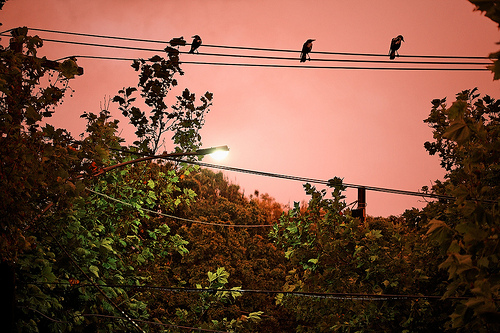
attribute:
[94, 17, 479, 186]
sky — pink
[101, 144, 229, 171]
street light — on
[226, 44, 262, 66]
wires — electrical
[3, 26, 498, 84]
wires — three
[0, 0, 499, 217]
sky — beautiful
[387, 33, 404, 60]
bird — black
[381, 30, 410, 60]
bird — small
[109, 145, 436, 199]
wire — electrical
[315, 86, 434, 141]
sky — beautiful, color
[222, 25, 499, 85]
wire — telephone wire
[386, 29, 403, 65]
bird — four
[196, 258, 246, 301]
foilage — green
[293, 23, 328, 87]
bird — small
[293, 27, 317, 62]
bird — small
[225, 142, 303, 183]
cow — small, white, black, back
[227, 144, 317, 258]
cow — back, small, black, white